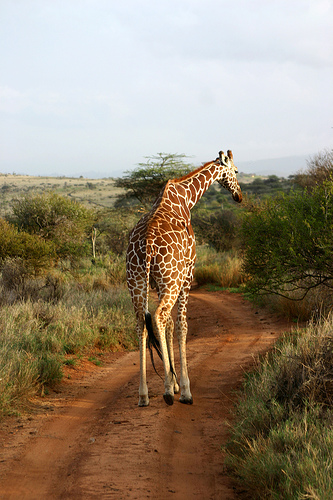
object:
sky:
[0, 0, 333, 177]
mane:
[163, 160, 218, 194]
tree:
[239, 172, 333, 298]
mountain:
[240, 154, 333, 173]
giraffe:
[126, 148, 242, 401]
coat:
[127, 181, 194, 313]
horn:
[219, 150, 224, 157]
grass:
[0, 182, 126, 417]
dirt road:
[0, 285, 300, 500]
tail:
[146, 236, 176, 382]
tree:
[0, 215, 54, 277]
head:
[218, 150, 242, 203]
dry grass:
[226, 305, 333, 498]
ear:
[222, 155, 229, 166]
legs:
[177, 297, 189, 375]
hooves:
[138, 396, 149, 407]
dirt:
[73, 423, 169, 500]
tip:
[144, 314, 180, 389]